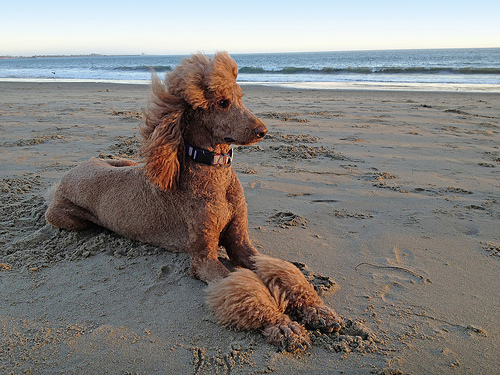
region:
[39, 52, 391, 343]
There is a poodle on the beach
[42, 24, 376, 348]
There is a poodle in the sand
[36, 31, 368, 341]
The poodle is brown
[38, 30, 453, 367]
The photo was taken on the beach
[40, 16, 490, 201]
The ocean is in the background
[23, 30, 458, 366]
There is a brown poodle in the sand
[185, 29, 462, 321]
There are waves in the background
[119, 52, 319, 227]
The poodle has a collar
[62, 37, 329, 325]
The brown Poodle has a collar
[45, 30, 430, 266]
The photo was taken during the daytime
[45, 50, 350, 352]
a dog lying on the beach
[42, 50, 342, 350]
the dog has a collar on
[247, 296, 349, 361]
the paws of a dog are covered with sand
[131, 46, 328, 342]
the hair on the dog is blowing in the wind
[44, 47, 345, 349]
the dog has a french poodle cut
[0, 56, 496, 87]
a wave is hitting the beach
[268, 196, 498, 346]
foot prints in the wet sand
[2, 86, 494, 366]
the beach sand is wet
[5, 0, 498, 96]
the sky at the beach is clear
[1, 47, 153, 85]
land can be seen across the water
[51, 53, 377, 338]
brown poodle on beach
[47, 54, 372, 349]
brown dog on beach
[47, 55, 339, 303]
brown dog with black collar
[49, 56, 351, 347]
brown dog with black collar on beach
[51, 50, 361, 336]
brown dog with black collar laying on beach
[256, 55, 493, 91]
waves on the beach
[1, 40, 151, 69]
land in distance across bay area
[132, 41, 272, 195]
dog's longer fur being blown by the wind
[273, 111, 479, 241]
wet sand on the beach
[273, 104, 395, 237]
wet sand with footprints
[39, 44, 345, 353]
The dog lying on the beack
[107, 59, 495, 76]
The wave in the ocean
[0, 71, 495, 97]
Where the water meets the sand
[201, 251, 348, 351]
Tufts of hair on the dog's legs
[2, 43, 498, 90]
The ocean in the background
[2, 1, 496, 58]
The sky in the background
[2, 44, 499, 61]
The horizon line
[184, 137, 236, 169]
Collar around the dog's neck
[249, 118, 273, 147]
The nose of the dog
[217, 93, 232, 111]
The dog's eye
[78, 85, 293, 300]
the dog is brown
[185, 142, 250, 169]
the dog has a colar on its neck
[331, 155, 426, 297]
the sand is wet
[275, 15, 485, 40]
the sun is setting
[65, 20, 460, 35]
the sky is cloudless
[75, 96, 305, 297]
the dog is sitting down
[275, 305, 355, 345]
the claws can be seen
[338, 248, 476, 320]
the sand is brown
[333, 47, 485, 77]
the water is calm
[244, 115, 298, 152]
the nose is black